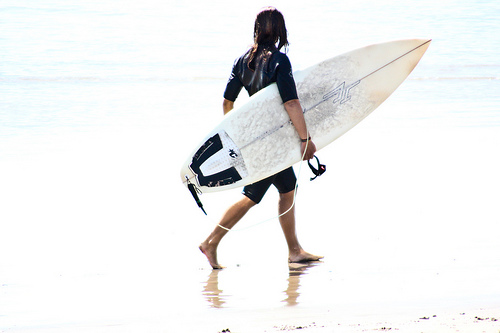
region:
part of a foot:
[281, 244, 313, 271]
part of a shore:
[381, 203, 418, 245]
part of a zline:
[232, 133, 266, 173]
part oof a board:
[259, 98, 272, 119]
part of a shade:
[270, 255, 290, 281]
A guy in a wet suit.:
[198, 5, 325, 270]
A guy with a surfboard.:
[179, 8, 434, 271]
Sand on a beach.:
[5, 128, 497, 331]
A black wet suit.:
[223, 43, 298, 205]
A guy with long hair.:
[197, 5, 326, 271]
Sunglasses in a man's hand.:
[306, 153, 328, 181]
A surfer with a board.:
[179, 7, 432, 270]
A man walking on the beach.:
[197, 4, 317, 271]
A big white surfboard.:
[178, 37, 433, 194]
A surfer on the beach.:
[197, 6, 324, 271]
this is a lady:
[196, 0, 331, 268]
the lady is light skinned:
[290, 103, 307, 122]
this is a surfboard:
[318, 53, 379, 114]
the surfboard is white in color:
[243, 114, 292, 164]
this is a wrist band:
[301, 134, 316, 141]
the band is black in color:
[293, 137, 316, 145]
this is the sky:
[55, 16, 173, 48]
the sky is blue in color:
[41, 13, 137, 48]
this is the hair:
[258, 18, 290, 44]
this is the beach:
[364, 235, 466, 320]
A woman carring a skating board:
[237, 4, 329, 280]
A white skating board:
[212, 31, 413, 183]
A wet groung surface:
[90, 271, 181, 325]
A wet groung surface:
[212, 275, 329, 312]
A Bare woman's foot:
[280, 194, 324, 269]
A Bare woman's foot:
[190, 188, 261, 272]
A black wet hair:
[237, 4, 287, 62]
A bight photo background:
[71, 18, 168, 118]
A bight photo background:
[414, 30, 476, 132]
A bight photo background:
[347, 163, 469, 250]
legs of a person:
[198, 199, 333, 286]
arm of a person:
[260, 62, 326, 164]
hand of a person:
[291, 138, 319, 161]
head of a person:
[233, 2, 296, 51]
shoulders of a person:
[241, 52, 298, 73]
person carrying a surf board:
[157, 24, 447, 158]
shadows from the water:
[192, 263, 315, 312]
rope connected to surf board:
[166, 108, 335, 245]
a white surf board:
[162, 43, 432, 207]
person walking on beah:
[166, 0, 444, 257]